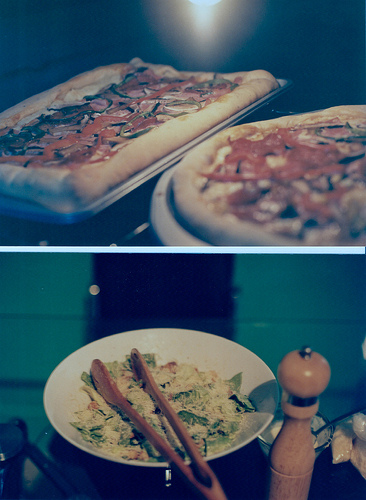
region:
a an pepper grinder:
[267, 346, 333, 499]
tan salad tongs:
[89, 348, 226, 498]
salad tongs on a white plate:
[42, 326, 277, 498]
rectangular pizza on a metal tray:
[1, 57, 281, 221]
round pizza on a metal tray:
[150, 104, 364, 247]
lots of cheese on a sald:
[74, 353, 255, 460]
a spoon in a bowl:
[258, 405, 364, 458]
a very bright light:
[154, 0, 253, 51]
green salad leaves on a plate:
[75, 352, 257, 461]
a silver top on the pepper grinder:
[277, 346, 327, 364]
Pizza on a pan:
[13, 66, 225, 196]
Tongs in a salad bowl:
[71, 328, 223, 489]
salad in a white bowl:
[121, 361, 218, 450]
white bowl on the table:
[39, 330, 310, 488]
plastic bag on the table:
[324, 413, 362, 474]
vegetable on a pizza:
[31, 62, 146, 173]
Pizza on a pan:
[199, 113, 351, 224]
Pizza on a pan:
[38, 78, 348, 263]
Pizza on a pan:
[103, 57, 271, 223]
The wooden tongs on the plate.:
[93, 343, 227, 498]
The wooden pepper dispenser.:
[274, 347, 321, 496]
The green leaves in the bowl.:
[85, 353, 253, 447]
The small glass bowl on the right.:
[263, 398, 330, 468]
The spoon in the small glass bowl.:
[314, 389, 361, 453]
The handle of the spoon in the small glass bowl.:
[320, 399, 364, 424]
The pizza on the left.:
[3, 47, 303, 212]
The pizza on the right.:
[164, 105, 362, 237]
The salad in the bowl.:
[96, 355, 236, 444]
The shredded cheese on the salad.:
[76, 352, 248, 451]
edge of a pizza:
[192, 102, 202, 114]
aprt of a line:
[298, 471, 303, 475]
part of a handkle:
[190, 443, 205, 462]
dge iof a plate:
[225, 422, 256, 463]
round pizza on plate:
[198, 125, 363, 246]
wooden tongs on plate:
[90, 323, 261, 497]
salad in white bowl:
[56, 319, 267, 473]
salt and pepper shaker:
[270, 333, 326, 499]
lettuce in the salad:
[183, 387, 227, 440]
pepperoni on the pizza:
[246, 125, 298, 177]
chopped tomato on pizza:
[61, 105, 123, 146]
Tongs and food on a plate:
[89, 349, 255, 498]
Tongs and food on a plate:
[36, 308, 297, 497]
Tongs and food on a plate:
[34, 315, 287, 494]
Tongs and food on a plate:
[34, 319, 296, 496]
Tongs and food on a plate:
[20, 309, 304, 498]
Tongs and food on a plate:
[42, 321, 296, 499]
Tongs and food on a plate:
[32, 332, 277, 496]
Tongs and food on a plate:
[46, 317, 283, 498]